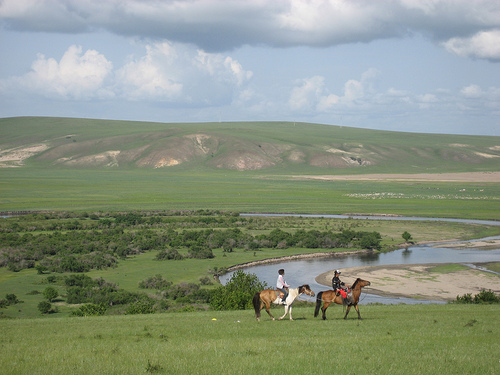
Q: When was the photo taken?
A: Day time.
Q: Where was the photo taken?
A: In the country.